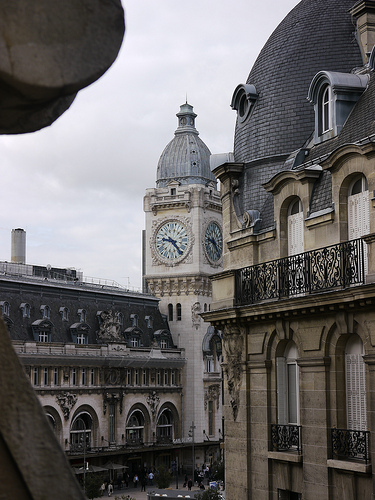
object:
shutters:
[287, 212, 306, 298]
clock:
[203, 218, 225, 267]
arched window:
[279, 192, 305, 297]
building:
[199, 0, 374, 498]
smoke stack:
[9, 229, 27, 265]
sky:
[0, 0, 299, 295]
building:
[0, 92, 225, 495]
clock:
[153, 221, 191, 263]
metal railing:
[268, 422, 302, 452]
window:
[277, 355, 301, 423]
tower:
[142, 94, 224, 297]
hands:
[171, 242, 183, 258]